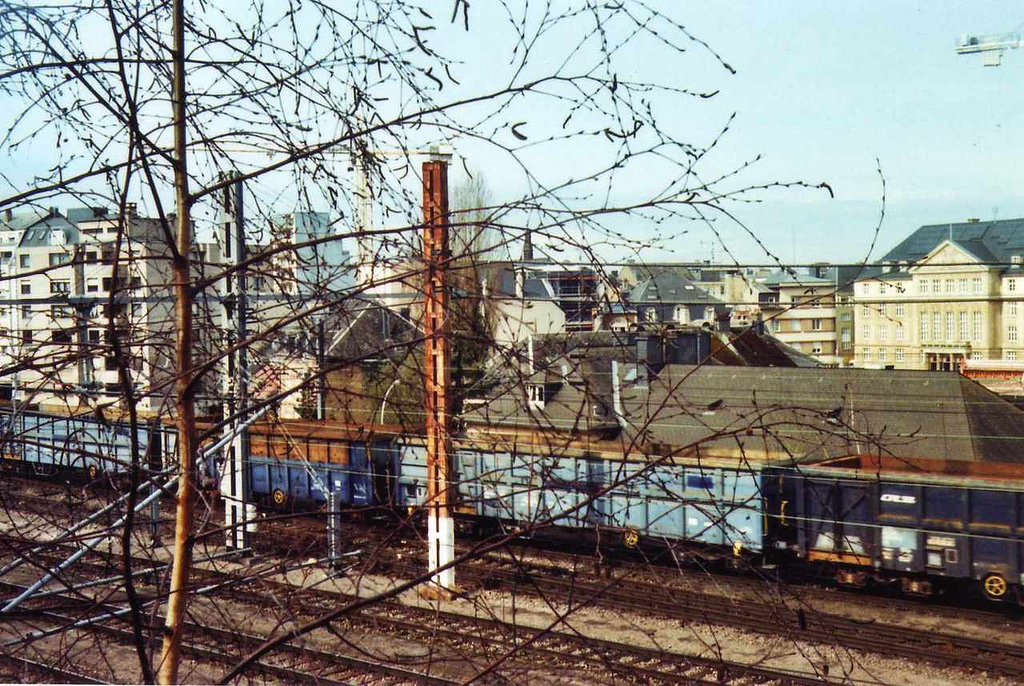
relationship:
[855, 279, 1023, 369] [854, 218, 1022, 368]
wall on building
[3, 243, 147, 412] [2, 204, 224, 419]
wall on building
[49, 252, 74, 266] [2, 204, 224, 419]
window on building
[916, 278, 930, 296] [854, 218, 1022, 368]
window on building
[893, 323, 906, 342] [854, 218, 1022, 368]
window on building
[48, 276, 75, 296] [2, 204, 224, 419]
window on building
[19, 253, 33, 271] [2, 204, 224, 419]
window on building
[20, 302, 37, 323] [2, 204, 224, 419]
window on building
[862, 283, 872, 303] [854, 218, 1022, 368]
window on building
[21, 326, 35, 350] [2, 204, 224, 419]
window on building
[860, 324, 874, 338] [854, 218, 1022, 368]
window on building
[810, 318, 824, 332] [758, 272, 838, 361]
window on side of building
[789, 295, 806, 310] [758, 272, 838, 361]
window on side of building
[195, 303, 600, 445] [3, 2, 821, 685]
branch on right side of tree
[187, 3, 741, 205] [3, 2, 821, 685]
branch on right side of tree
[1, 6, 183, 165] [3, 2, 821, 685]
branch on left side of tree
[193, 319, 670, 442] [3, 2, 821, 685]
branch on right side of tree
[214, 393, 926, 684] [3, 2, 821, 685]
branch on tree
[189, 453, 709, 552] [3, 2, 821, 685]
branch on tree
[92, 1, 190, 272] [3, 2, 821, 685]
branch on tree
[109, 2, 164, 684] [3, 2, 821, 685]
branch on tree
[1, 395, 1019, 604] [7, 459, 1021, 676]
train on track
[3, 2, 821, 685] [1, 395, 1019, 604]
tree in front of train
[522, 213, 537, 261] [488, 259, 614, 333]
spire on top of building